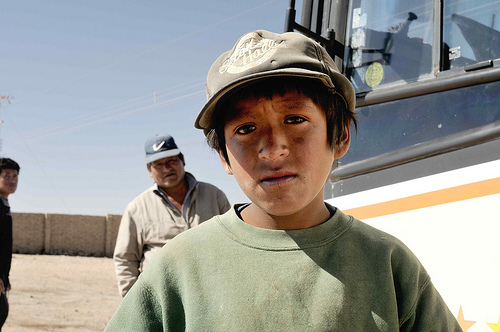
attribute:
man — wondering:
[108, 129, 237, 296]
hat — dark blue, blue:
[139, 131, 184, 167]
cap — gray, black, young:
[190, 27, 361, 134]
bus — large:
[284, 0, 500, 194]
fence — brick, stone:
[9, 208, 121, 260]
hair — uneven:
[199, 77, 362, 160]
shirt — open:
[111, 175, 233, 283]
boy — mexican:
[103, 27, 463, 331]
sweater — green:
[101, 204, 461, 331]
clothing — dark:
[0, 194, 17, 330]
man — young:
[1, 154, 24, 327]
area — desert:
[18, 243, 101, 328]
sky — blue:
[3, 5, 197, 126]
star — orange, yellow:
[456, 300, 478, 331]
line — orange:
[355, 175, 499, 214]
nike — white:
[152, 141, 166, 155]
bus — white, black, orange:
[352, 4, 494, 241]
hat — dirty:
[202, 19, 345, 108]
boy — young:
[119, 13, 453, 329]